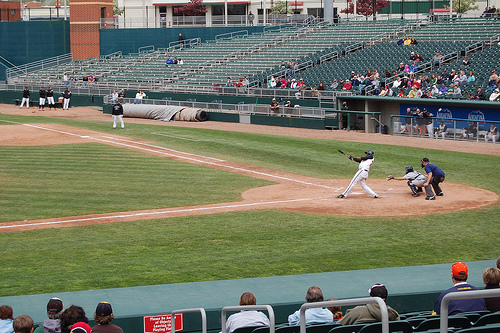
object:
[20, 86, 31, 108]
players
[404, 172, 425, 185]
shirt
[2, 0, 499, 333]
stadium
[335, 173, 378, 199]
box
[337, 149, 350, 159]
bat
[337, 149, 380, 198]
baseball player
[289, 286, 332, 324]
spectator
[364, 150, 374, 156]
helmet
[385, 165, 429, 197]
catcher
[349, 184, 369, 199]
home plate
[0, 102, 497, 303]
field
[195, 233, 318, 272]
grass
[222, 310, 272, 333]
shirt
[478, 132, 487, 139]
players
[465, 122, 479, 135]
players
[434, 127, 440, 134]
players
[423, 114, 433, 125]
players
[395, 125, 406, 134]
players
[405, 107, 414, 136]
coaches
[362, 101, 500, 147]
dugout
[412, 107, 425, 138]
coach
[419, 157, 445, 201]
spectator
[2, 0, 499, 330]
baseball game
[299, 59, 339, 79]
seats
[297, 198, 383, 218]
sand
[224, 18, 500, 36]
empty seats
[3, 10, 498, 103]
stands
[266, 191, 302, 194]
dirt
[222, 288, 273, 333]
man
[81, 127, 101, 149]
base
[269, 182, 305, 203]
dirt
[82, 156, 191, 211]
turf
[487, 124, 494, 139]
player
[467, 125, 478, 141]
player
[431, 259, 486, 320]
man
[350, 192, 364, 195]
plate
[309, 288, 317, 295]
bald spot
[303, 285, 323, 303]
head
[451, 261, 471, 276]
cap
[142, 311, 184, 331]
sign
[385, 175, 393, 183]
ball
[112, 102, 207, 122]
rolls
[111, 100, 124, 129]
ball player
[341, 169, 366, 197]
legs